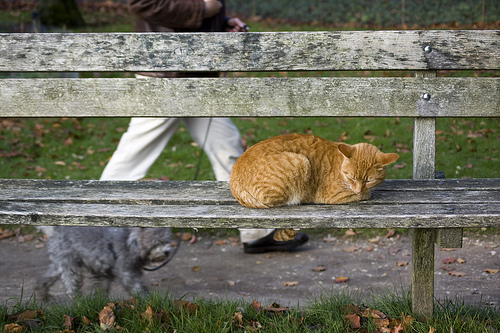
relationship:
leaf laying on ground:
[94, 301, 120, 331] [0, 32, 499, 322]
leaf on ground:
[94, 301, 120, 331] [0, 32, 499, 322]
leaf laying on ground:
[51, 157, 68, 169] [0, 32, 499, 322]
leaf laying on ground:
[341, 309, 365, 332] [0, 32, 499, 322]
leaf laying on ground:
[230, 311, 248, 331] [0, 32, 499, 322]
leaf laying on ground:
[225, 275, 241, 288] [0, 32, 499, 322]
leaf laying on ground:
[449, 269, 467, 278] [0, 32, 499, 322]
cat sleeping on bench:
[233, 130, 395, 213] [0, 32, 499, 322]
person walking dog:
[97, 1, 308, 254] [29, 220, 173, 308]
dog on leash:
[29, 220, 173, 308] [137, 117, 227, 275]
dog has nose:
[29, 220, 173, 308] [163, 249, 170, 257]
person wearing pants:
[97, 1, 308, 254] [93, 73, 282, 249]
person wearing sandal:
[97, 1, 308, 254] [241, 227, 310, 255]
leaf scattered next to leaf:
[94, 301, 120, 331] [230, 311, 248, 331]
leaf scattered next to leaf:
[341, 309, 365, 332] [330, 273, 350, 287]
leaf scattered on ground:
[51, 157, 68, 169] [0, 32, 499, 322]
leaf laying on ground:
[34, 122, 44, 129] [0, 32, 499, 322]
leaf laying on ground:
[393, 160, 408, 171] [0, 32, 499, 322]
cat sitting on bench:
[233, 130, 395, 213] [0, 32, 499, 322]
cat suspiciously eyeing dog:
[233, 130, 395, 213] [29, 220, 173, 308]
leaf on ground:
[450, 124, 460, 134] [0, 32, 499, 322]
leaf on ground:
[361, 128, 381, 142] [0, 32, 499, 322]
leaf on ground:
[393, 160, 408, 171] [0, 32, 499, 322]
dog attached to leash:
[29, 220, 173, 308] [137, 117, 227, 275]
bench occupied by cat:
[0, 32, 499, 322] [233, 130, 395, 213]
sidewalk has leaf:
[1, 224, 497, 319] [225, 275, 241, 288]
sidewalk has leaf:
[1, 224, 497, 319] [330, 273, 350, 287]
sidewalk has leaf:
[1, 224, 497, 319] [449, 269, 467, 278]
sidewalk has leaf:
[1, 224, 497, 319] [284, 278, 298, 288]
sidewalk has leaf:
[1, 224, 497, 319] [343, 243, 361, 255]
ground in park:
[0, 32, 499, 322] [1, 2, 499, 330]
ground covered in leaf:
[0, 32, 499, 322] [94, 301, 120, 331]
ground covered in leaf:
[0, 32, 499, 322] [225, 275, 241, 288]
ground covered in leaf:
[0, 32, 499, 322] [361, 128, 381, 142]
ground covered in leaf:
[0, 32, 499, 322] [450, 124, 460, 134]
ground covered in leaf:
[0, 32, 499, 322] [34, 122, 44, 129]